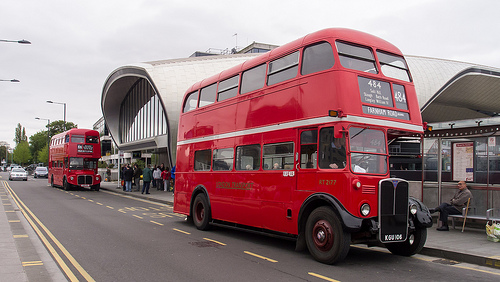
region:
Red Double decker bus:
[173, 28, 432, 264]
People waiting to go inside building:
[117, 158, 173, 195]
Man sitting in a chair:
[431, 176, 477, 234]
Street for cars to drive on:
[0, 174, 118, 272]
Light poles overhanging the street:
[0, 27, 37, 95]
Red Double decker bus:
[47, 126, 102, 192]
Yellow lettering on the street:
[119, 200, 177, 226]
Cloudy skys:
[33, 3, 498, 32]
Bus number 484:
[392, 80, 409, 108]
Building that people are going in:
[98, 72, 175, 153]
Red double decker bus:
[172, 26, 433, 265]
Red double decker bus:
[45, 127, 102, 192]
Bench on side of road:
[428, 208, 498, 235]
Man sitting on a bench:
[426, 177, 473, 233]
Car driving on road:
[7, 163, 29, 182]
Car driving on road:
[32, 164, 48, 177]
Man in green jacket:
[139, 162, 154, 194]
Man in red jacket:
[160, 163, 173, 193]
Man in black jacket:
[120, 158, 136, 194]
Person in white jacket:
[150, 162, 162, 189]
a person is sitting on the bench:
[425, 178, 497, 235]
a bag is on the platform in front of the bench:
[442, 193, 499, 241]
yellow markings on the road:
[37, 188, 172, 252]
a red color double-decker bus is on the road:
[171, 26, 431, 263]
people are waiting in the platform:
[106, 153, 171, 193]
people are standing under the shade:
[98, 61, 175, 198]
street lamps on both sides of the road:
[0, 33, 70, 180]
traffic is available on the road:
[3, 125, 104, 193]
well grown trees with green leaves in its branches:
[11, 116, 78, 169]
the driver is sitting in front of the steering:
[313, 118, 373, 178]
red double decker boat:
[148, 74, 436, 279]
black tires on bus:
[283, 176, 367, 263]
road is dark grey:
[100, 259, 280, 280]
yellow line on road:
[42, 220, 317, 270]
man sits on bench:
[422, 166, 470, 235]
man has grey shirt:
[458, 182, 472, 203]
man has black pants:
[427, 205, 472, 227]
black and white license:
[372, 226, 400, 245]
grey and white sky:
[47, 16, 129, 78]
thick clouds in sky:
[34, 10, 86, 90]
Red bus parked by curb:
[169, 26, 429, 263]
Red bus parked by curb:
[46, 127, 101, 191]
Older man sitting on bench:
[423, 178, 473, 232]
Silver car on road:
[7, 163, 29, 181]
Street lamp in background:
[44, 92, 70, 132]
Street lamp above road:
[0, 34, 32, 48]